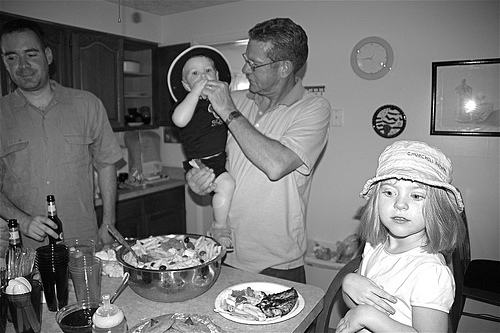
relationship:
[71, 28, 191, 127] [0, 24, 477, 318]
cabinet in kitchen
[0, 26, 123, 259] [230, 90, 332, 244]
man wearing shirt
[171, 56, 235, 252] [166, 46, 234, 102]
baby wears hat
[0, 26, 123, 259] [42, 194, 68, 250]
man holds beer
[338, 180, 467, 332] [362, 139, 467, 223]
girl wears hat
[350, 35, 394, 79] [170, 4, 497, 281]
clock on wall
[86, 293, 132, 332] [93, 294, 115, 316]
bottle has nipple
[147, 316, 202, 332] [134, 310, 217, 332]
cookies on plate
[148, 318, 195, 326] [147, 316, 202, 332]
chocolate on cookies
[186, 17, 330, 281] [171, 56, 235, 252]
man holds baby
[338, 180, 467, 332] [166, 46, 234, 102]
girl wears hat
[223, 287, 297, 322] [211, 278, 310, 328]
food on plate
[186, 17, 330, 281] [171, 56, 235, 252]
man feeds baby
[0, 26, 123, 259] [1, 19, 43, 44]
man has hair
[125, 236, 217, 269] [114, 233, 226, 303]
fruit salad in bowl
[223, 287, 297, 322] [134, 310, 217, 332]
food on plate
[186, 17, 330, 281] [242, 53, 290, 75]
man wears glasses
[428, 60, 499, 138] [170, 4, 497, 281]
picture frame on wall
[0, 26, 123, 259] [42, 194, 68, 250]
man holding beer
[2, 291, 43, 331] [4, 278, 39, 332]
cup filled with spoons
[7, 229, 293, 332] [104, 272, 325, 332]
food and drinks on counter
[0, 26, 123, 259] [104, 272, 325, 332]
man next to counter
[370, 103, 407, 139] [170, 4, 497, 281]
picture on wall